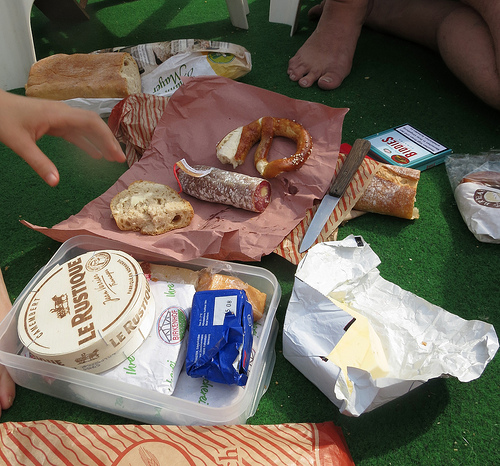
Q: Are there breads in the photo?
A: Yes, there is a bread.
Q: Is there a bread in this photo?
A: Yes, there is a bread.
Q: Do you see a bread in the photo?
A: Yes, there is a bread.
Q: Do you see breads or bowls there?
A: Yes, there is a bread.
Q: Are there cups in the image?
A: No, there are no cups.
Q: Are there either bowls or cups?
A: No, there are no cups or bowls.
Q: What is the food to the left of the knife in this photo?
A: The food is a bread.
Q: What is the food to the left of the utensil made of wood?
A: The food is a bread.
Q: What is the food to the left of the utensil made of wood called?
A: The food is a bread.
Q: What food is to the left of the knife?
A: The food is a bread.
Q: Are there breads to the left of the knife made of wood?
A: Yes, there is a bread to the left of the knife.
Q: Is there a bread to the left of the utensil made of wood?
A: Yes, there is a bread to the left of the knife.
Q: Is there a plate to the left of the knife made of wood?
A: No, there is a bread to the left of the knife.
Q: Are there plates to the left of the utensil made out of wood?
A: No, there is a bread to the left of the knife.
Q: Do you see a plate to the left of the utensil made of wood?
A: No, there is a bread to the left of the knife.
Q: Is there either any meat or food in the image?
A: Yes, there is food.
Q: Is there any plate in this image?
A: No, there are no plates.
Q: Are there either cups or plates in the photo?
A: No, there are no plates or cups.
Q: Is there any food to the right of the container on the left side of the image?
A: Yes, there is food to the right of the container.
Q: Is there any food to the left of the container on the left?
A: No, the food is to the right of the container.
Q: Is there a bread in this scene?
A: Yes, there is a bread.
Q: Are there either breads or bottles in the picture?
A: Yes, there is a bread.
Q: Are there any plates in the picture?
A: No, there are no plates.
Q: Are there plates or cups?
A: No, there are no plates or cups.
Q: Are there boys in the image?
A: No, there are no boys.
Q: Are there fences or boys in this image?
A: No, there are no boys or fences.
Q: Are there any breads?
A: Yes, there is a bread.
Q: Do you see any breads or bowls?
A: Yes, there is a bread.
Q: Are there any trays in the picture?
A: No, there are no trays.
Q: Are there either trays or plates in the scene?
A: No, there are no trays or plates.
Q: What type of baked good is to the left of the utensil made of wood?
A: The food is a bread.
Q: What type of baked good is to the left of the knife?
A: The food is a bread.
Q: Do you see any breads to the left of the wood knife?
A: Yes, there is a bread to the left of the knife.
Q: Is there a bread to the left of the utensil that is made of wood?
A: Yes, there is a bread to the left of the knife.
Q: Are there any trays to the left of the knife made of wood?
A: No, there is a bread to the left of the knife.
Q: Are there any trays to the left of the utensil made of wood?
A: No, there is a bread to the left of the knife.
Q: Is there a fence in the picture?
A: No, there are no fences.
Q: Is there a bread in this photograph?
A: Yes, there is a bread.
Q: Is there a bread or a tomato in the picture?
A: Yes, there is a bread.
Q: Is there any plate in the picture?
A: No, there are no plates.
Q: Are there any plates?
A: No, there are no plates.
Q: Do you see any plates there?
A: No, there are no plates.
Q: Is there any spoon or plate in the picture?
A: No, there are no plates or spoons.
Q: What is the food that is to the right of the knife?
A: The food is a bread.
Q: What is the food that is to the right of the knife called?
A: The food is a bread.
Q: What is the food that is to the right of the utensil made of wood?
A: The food is a bread.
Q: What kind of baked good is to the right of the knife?
A: The food is a bread.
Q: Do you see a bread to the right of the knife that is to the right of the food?
A: Yes, there is a bread to the right of the knife.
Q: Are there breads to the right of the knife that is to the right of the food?
A: Yes, there is a bread to the right of the knife.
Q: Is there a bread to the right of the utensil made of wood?
A: Yes, there is a bread to the right of the knife.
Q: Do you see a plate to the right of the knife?
A: No, there is a bread to the right of the knife.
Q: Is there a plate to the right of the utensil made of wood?
A: No, there is a bread to the right of the knife.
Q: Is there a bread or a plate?
A: Yes, there is a bread.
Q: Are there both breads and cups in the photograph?
A: No, there is a bread but no cups.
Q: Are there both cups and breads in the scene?
A: No, there is a bread but no cups.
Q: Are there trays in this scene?
A: No, there are no trays.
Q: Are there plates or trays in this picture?
A: No, there are no trays or plates.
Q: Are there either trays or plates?
A: No, there are no trays or plates.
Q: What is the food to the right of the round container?
A: The food is a bread.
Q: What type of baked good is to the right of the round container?
A: The food is a bread.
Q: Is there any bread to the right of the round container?
A: Yes, there is a bread to the right of the container.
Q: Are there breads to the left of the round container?
A: No, the bread is to the right of the container.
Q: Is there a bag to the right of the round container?
A: No, there is a bread to the right of the container.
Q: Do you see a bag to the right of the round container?
A: No, there is a bread to the right of the container.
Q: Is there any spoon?
A: No, there are no spoons.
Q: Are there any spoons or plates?
A: No, there are no spoons or plates.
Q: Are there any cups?
A: No, there are no cups.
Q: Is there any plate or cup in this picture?
A: No, there are no cups or plates.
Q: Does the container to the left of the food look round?
A: Yes, the container is round.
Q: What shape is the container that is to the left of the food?
A: The container is round.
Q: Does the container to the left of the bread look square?
A: No, the container is round.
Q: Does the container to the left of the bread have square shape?
A: No, the container is round.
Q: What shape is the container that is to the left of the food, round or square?
A: The container is round.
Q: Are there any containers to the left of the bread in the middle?
A: Yes, there is a container to the left of the bread.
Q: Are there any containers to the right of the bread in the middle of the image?
A: No, the container is to the left of the bread.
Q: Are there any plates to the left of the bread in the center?
A: No, there is a container to the left of the bread.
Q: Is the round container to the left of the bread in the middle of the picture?
A: Yes, the container is to the left of the bread.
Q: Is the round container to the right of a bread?
A: No, the container is to the left of a bread.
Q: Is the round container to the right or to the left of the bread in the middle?
A: The container is to the left of the bread.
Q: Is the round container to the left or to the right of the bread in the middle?
A: The container is to the left of the bread.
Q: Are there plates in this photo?
A: No, there are no plates.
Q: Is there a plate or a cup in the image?
A: No, there are no plates or cups.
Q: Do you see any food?
A: Yes, there is food.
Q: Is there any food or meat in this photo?
A: Yes, there is food.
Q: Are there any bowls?
A: No, there are no bowls.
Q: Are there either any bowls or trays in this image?
A: No, there are no bowls or trays.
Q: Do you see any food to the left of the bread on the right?
A: Yes, there is food to the left of the bread.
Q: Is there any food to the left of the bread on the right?
A: Yes, there is food to the left of the bread.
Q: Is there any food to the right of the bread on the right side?
A: No, the food is to the left of the bread.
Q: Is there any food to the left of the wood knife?
A: Yes, there is food to the left of the knife.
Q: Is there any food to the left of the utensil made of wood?
A: Yes, there is food to the left of the knife.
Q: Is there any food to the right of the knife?
A: No, the food is to the left of the knife.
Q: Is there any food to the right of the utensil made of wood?
A: No, the food is to the left of the knife.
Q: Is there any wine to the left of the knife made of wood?
A: No, there is food to the left of the knife.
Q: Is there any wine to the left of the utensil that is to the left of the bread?
A: No, there is food to the left of the knife.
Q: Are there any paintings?
A: No, there are no paintings.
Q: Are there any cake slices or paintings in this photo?
A: No, there are no paintings or cake slices.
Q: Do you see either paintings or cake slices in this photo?
A: No, there are no paintings or cake slices.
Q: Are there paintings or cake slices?
A: No, there are no paintings or cake slices.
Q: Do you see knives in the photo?
A: Yes, there is a knife.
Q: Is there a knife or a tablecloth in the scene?
A: Yes, there is a knife.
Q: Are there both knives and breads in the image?
A: Yes, there are both a knife and a bread.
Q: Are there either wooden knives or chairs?
A: Yes, there is a wood knife.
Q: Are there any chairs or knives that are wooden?
A: Yes, the knife is wooden.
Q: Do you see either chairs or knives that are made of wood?
A: Yes, the knife is made of wood.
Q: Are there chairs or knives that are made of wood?
A: Yes, the knife is made of wood.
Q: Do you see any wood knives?
A: Yes, there is a wood knife.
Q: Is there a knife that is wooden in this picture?
A: Yes, there is a wood knife.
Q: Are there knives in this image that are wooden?
A: Yes, there is a knife that is wooden.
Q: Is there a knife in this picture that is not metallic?
A: Yes, there is a wooden knife.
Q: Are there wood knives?
A: Yes, there is a knife that is made of wood.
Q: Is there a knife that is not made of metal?
A: Yes, there is a knife that is made of wood.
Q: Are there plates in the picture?
A: No, there are no plates.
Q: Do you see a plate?
A: No, there are no plates.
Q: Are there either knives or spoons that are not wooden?
A: No, there is a knife but it is wooden.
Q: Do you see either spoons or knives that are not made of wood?
A: No, there is a knife but it is made of wood.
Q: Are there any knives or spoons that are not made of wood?
A: No, there is a knife but it is made of wood.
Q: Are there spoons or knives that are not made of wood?
A: No, there is a knife but it is made of wood.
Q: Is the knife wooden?
A: Yes, the knife is wooden.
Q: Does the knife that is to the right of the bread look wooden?
A: Yes, the knife is wooden.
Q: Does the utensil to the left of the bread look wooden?
A: Yes, the knife is wooden.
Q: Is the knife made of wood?
A: Yes, the knife is made of wood.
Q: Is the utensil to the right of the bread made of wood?
A: Yes, the knife is made of wood.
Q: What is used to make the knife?
A: The knife is made of wood.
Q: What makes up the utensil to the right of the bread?
A: The knife is made of wood.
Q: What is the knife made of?
A: The knife is made of wood.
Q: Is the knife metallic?
A: No, the knife is wooden.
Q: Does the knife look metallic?
A: No, the knife is wooden.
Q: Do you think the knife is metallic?
A: No, the knife is wooden.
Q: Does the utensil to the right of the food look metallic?
A: No, the knife is wooden.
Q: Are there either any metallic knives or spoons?
A: No, there is a knife but it is wooden.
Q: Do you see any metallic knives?
A: No, there is a knife but it is wooden.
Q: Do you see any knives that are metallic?
A: No, there is a knife but it is wooden.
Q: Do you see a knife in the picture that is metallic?
A: No, there is a knife but it is wooden.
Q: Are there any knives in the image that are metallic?
A: No, there is a knife but it is wooden.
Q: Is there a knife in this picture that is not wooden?
A: No, there is a knife but it is wooden.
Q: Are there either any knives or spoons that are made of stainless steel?
A: No, there is a knife but it is made of wood.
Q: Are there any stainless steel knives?
A: No, there is a knife but it is made of wood.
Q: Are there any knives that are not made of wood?
A: No, there is a knife but it is made of wood.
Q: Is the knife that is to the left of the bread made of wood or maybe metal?
A: The knife is made of wood.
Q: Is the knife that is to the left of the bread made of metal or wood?
A: The knife is made of wood.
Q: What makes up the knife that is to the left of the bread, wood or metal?
A: The knife is made of wood.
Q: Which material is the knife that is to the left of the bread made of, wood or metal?
A: The knife is made of wood.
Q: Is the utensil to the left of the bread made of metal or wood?
A: The knife is made of wood.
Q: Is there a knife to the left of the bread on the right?
A: Yes, there is a knife to the left of the bread.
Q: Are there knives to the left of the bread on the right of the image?
A: Yes, there is a knife to the left of the bread.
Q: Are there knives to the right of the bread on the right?
A: No, the knife is to the left of the bread.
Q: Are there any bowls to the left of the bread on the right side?
A: No, there is a knife to the left of the bread.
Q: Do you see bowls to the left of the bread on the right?
A: No, there is a knife to the left of the bread.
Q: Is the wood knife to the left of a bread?
A: Yes, the knife is to the left of a bread.